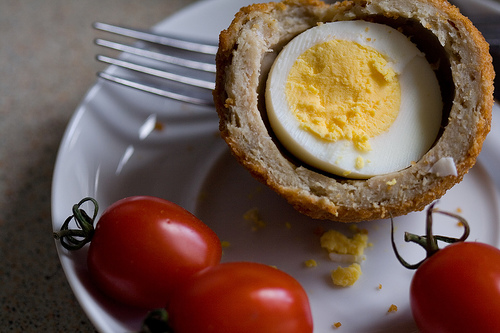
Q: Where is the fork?
A: In the back.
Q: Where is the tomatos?
A: In the front.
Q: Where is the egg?
A: In the middle.